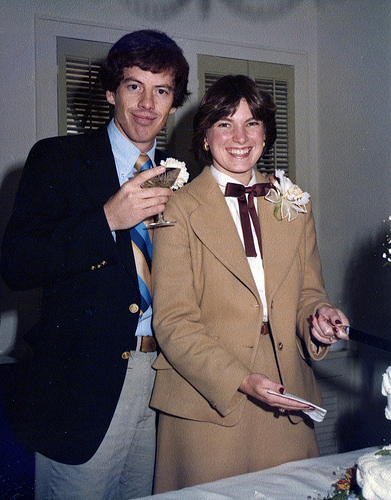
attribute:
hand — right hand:
[100, 164, 173, 233]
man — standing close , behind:
[9, 26, 173, 498]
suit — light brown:
[149, 152, 357, 471]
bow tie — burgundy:
[235, 168, 296, 240]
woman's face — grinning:
[182, 74, 305, 185]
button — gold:
[128, 300, 140, 319]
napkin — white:
[263, 384, 330, 424]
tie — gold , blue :
[125, 149, 162, 323]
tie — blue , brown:
[130, 156, 158, 320]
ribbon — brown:
[224, 179, 274, 258]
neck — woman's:
[210, 161, 259, 189]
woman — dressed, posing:
[146, 71, 352, 473]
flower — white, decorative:
[258, 169, 313, 223]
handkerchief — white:
[266, 386, 328, 424]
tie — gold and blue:
[122, 154, 168, 313]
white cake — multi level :
[359, 365, 389, 499]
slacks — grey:
[18, 334, 166, 498]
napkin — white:
[266, 388, 328, 424]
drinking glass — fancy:
[147, 167, 181, 190]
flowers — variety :
[305, 462, 364, 498]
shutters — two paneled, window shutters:
[56, 37, 164, 147]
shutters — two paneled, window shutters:
[195, 48, 301, 165]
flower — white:
[267, 168, 312, 220]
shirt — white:
[211, 164, 269, 321]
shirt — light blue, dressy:
[107, 116, 155, 344]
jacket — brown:
[150, 163, 336, 426]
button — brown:
[207, 399, 218, 409]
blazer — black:
[17, 116, 152, 473]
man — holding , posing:
[0, 22, 196, 497]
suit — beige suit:
[163, 166, 345, 495]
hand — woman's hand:
[228, 364, 309, 430]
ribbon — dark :
[216, 181, 298, 268]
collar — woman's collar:
[187, 166, 275, 202]